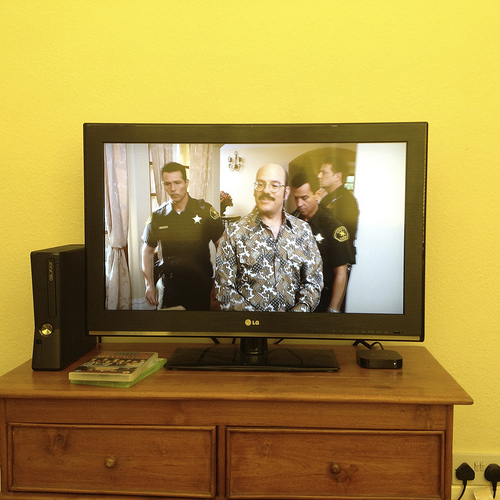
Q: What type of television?
A: Flat screen.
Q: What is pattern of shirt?
A: Floral.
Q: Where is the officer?
A: On television.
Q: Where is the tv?
A: Front of wall.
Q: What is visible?
A: Cupboard.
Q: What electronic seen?
A: Television.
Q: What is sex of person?
A: A man.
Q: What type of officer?
A: Police.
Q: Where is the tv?
A: On dresser.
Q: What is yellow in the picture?
A: The wall.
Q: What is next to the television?
A: Disc player.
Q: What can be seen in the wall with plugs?
A: Electrical outlet.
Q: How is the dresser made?
A: Of wood.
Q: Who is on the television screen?
A: 4 men.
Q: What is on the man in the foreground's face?
A: Glasses.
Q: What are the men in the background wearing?
A: Uniforms.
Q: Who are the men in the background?
A: Police officers.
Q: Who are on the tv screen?
A: Men in police uniforms.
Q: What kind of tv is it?
A: Flat screen.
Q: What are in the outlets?
A: Two plugs.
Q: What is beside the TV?
A: An Xbox.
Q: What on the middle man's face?
A: Mustache.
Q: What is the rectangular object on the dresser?
A: A television.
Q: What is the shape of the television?
A: A rectangle.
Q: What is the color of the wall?
A: Yellow.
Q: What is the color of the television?
A: Black.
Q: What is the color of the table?
A: Brown.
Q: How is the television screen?
A: On.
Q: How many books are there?
A: 2.